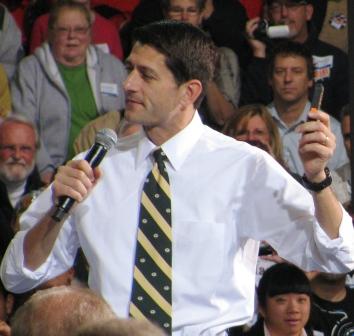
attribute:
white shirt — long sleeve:
[5, 119, 342, 310]